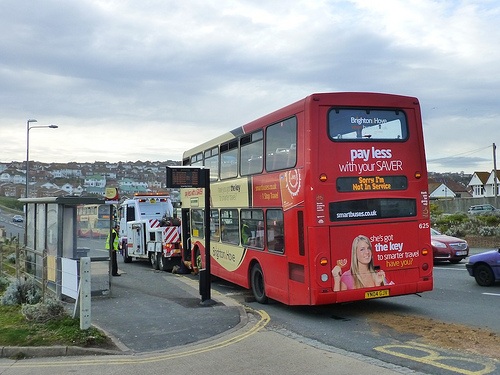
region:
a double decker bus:
[177, 90, 434, 306]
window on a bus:
[325, 102, 410, 145]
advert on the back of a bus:
[332, 229, 422, 291]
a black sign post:
[165, 165, 211, 306]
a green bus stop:
[16, 194, 115, 299]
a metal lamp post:
[27, 117, 57, 199]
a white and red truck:
[115, 189, 182, 266]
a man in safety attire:
[105, 226, 123, 275]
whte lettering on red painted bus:
[335, 143, 405, 171]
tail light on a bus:
[318, 257, 326, 266]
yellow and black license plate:
[358, 283, 403, 300]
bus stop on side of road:
[0, 168, 122, 348]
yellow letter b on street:
[361, 328, 498, 368]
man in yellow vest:
[78, 212, 128, 282]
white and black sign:
[33, 250, 103, 373]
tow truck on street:
[90, 185, 175, 308]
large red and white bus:
[154, 113, 446, 344]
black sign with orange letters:
[157, 158, 237, 328]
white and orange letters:
[309, 141, 410, 197]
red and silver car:
[407, 218, 478, 285]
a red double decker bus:
[174, 89, 434, 315]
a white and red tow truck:
[112, 188, 179, 271]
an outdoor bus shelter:
[14, 194, 112, 301]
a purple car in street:
[464, 246, 499, 290]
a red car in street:
[428, 224, 471, 269]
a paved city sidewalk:
[41, 250, 242, 353]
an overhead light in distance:
[22, 114, 59, 187]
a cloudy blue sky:
[0, 0, 497, 160]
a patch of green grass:
[0, 250, 115, 352]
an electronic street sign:
[163, 162, 213, 303]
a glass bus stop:
[16, 194, 115, 296]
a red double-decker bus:
[184, 90, 434, 307]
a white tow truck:
[113, 189, 180, 273]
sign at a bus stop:
[163, 163, 213, 305]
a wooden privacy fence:
[431, 197, 496, 215]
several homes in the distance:
[0, 157, 174, 199]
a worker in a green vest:
[105, 223, 123, 276]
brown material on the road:
[364, 310, 499, 357]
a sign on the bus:
[334, 173, 409, 192]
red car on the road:
[428, 224, 470, 266]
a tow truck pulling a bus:
[101, 91, 452, 313]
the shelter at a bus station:
[10, 187, 115, 297]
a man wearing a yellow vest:
[100, 221, 129, 276]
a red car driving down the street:
[426, 223, 474, 268]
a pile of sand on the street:
[373, 305, 498, 364]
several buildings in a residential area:
[1, 158, 164, 189]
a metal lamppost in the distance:
[18, 114, 63, 198]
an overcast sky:
[4, 2, 498, 78]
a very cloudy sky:
[1, 0, 493, 85]